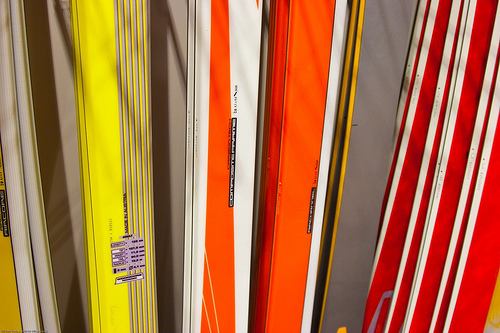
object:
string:
[202, 245, 224, 331]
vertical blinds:
[81, 5, 498, 330]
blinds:
[71, 0, 161, 333]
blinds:
[318, 0, 414, 333]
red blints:
[355, 0, 497, 332]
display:
[1, 0, 500, 333]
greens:
[98, 90, 468, 246]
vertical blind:
[156, 12, 498, 283]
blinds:
[0, 1, 160, 333]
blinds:
[181, 1, 350, 333]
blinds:
[307, 0, 419, 333]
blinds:
[360, 0, 498, 333]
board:
[79, 64, 114, 308]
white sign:
[227, 116, 238, 209]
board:
[364, 22, 395, 210]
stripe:
[316, 0, 389, 331]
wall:
[21, 27, 464, 297]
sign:
[0, 0, 160, 332]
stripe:
[185, 85, 204, 301]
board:
[327, 42, 442, 187]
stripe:
[200, 0, 242, 332]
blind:
[49, 115, 272, 326]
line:
[439, 61, 496, 328]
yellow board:
[59, 0, 155, 333]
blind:
[249, 0, 338, 332]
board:
[183, 64, 266, 215]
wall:
[4, 3, 499, 331]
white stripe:
[234, 131, 256, 250]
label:
[111, 234, 146, 285]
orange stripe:
[194, 1, 236, 331]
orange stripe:
[264, 0, 334, 332]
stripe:
[70, 0, 159, 331]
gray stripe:
[158, 54, 182, 221]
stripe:
[149, 0, 198, 331]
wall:
[85, 179, 136, 330]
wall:
[149, 99, 276, 323]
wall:
[192, 24, 312, 325]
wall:
[165, 4, 286, 330]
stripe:
[182, 3, 265, 333]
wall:
[360, 5, 485, 329]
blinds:
[55, 0, 172, 333]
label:
[306, 187, 316, 234]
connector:
[408, 2, 488, 318]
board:
[166, 4, 258, 331]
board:
[72, 7, 164, 330]